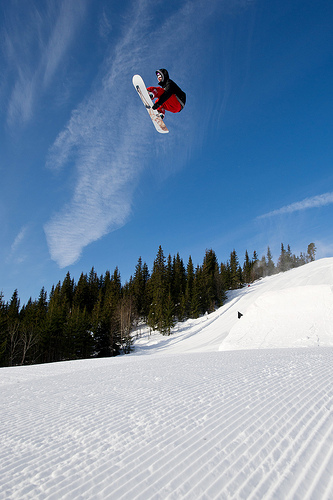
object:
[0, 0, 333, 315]
sky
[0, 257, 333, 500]
ground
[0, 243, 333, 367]
hill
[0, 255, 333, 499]
snow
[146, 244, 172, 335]
trees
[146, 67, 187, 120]
man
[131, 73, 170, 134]
board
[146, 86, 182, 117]
pants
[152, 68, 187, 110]
jacket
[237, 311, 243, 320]
flag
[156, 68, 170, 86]
head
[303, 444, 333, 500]
tracks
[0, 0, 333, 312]
clouds